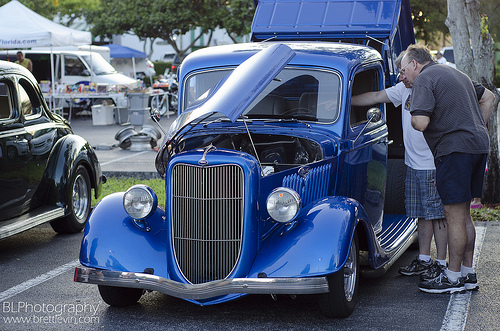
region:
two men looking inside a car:
[365, 47, 497, 299]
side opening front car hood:
[143, 38, 333, 178]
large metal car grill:
[166, 157, 253, 292]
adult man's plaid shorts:
[398, 153, 450, 227]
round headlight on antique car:
[119, 180, 159, 224]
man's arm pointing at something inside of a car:
[314, 77, 401, 124]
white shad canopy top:
[0, 1, 92, 58]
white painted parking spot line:
[0, 254, 80, 304]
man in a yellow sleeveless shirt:
[11, 50, 38, 75]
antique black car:
[1, 56, 113, 235]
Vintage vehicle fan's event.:
[2, 13, 403, 320]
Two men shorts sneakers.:
[356, 49, 490, 302]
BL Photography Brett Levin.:
[2, 293, 112, 325]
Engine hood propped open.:
[151, 55, 356, 177]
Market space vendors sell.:
[25, 17, 190, 125]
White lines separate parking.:
[1, 189, 498, 330]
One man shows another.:
[362, 42, 447, 116]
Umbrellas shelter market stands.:
[4, 0, 162, 65]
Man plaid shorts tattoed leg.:
[400, 154, 451, 236]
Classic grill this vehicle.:
[155, 145, 257, 305]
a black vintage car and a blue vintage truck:
[0, 60, 398, 314]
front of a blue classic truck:
[161, 117, 353, 294]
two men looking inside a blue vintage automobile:
[386, 49, 475, 287]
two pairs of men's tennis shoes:
[401, 255, 477, 290]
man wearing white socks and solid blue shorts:
[415, 55, 461, 288]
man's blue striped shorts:
[407, 167, 445, 221]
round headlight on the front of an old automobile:
[268, 189, 299, 221]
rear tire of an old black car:
[63, 168, 89, 228]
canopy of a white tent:
[0, 2, 90, 46]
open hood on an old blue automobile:
[195, 44, 327, 171]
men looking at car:
[89, 13, 491, 294]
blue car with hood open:
[76, 10, 417, 307]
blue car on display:
[75, 0, 429, 313]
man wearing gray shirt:
[400, 43, 492, 293]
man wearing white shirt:
[360, 62, 457, 289]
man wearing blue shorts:
[403, 49, 487, 294]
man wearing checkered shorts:
[355, 68, 451, 284]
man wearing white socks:
[402, 48, 495, 297]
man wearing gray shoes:
[403, 48, 486, 294]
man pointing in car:
[351, 53, 456, 284]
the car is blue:
[73, 17, 446, 329]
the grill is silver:
[153, 127, 258, 309]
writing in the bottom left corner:
[1, 282, 108, 323]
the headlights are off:
[94, 163, 317, 245]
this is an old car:
[88, 13, 445, 328]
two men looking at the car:
[365, 40, 485, 290]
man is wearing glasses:
[375, 41, 440, 91]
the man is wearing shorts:
[413, 142, 488, 227]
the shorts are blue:
[414, 132, 485, 226]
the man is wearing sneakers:
[410, 248, 489, 316]